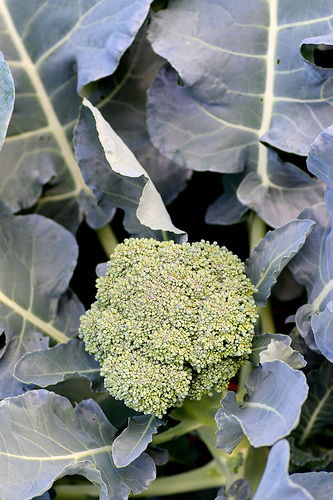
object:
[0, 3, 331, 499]
broccoli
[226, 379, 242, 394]
line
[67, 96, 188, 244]
leaf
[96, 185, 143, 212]
vein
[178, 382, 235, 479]
stem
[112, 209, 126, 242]
dark space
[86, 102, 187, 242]
underside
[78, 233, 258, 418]
floret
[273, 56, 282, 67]
spot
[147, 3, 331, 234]
leaf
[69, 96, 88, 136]
edge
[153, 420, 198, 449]
stalk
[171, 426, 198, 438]
edge